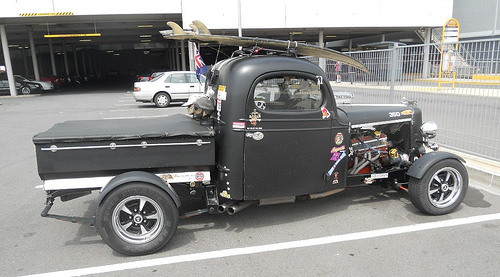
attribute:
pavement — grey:
[1, 82, 499, 277]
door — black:
[244, 72, 332, 198]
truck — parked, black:
[32, 55, 439, 216]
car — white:
[134, 71, 205, 108]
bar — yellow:
[44, 33, 100, 38]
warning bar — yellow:
[20, 12, 74, 19]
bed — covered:
[33, 118, 215, 180]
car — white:
[16, 75, 54, 89]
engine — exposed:
[349, 129, 410, 178]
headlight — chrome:
[420, 122, 441, 152]